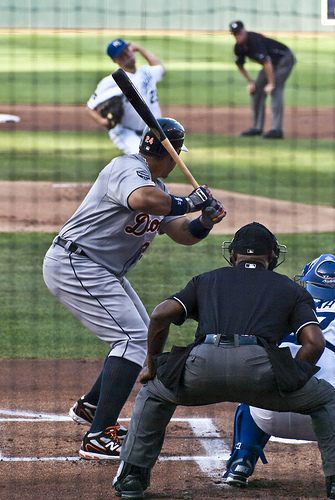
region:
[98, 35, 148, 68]
a guy wearing a blue hat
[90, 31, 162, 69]
a man throwing a baseball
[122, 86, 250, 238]
a man holding a baseball bat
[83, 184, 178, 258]
a man wearing a Dogers uniform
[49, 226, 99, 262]
a man wearing a black belt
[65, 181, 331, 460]
guys gathered at homebase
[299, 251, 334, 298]
a guy wearing a blue helmet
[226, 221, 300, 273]
an empire wearing a black hat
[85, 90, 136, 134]
a pitcher holding a catchers mit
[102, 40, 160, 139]
a pitcher standing on a pitcher's mond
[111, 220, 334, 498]
umpire in black crouched behind home plate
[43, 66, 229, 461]
baseball player standing at bat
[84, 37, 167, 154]
pitcher in white uniform throwing ball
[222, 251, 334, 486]
catcher in blue and white uniform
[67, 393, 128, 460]
pair of Nike athletic shoes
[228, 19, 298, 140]
umpire standing bent over with hands on knees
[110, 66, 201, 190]
wooden baseball bat with black end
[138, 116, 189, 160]
black baseball helmet with bearing number 24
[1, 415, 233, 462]
white lines marking batter's box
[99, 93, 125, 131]
baseball glove worn by pitcher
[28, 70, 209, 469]
this is a baseball player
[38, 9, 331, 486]
people playing a baseball game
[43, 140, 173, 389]
player wearing a grey uniform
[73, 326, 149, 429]
player wearing black socks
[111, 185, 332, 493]
this is an umpire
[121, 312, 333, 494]
umpire wearing grey pants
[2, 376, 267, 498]
white lines on ground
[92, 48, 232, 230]
player holding a bat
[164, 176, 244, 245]
a player wearing gloves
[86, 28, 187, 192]
a players pitching a ball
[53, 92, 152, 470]
man wearing gray uniform.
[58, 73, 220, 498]
man holding baseball bat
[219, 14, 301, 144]
man wearing black shirt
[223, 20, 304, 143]
man wearing black baseball cap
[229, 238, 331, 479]
man wearing blue helmet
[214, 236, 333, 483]
man wearing blue shin pads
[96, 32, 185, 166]
man wearing blue and white uniform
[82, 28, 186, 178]
man holding baseball mitt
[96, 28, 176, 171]
man wearing blue baseball cap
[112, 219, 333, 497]
Back of home plate umpire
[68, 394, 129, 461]
Orange, black and white New Balance baseball spikes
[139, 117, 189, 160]
Baseball helmet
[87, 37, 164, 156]
Left handed baseball pitcher throwing ball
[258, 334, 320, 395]
Ball bag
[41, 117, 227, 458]
Los Angeles Dodger hitting base ball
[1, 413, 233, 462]
Batters box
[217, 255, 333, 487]
Baseball catcher awaiting pitch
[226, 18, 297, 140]
Baseball umpire observing pitch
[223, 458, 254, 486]
Nike baseball spike